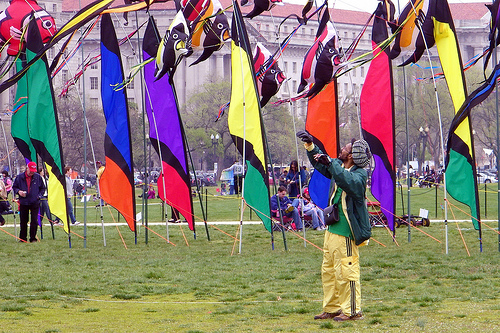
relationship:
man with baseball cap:
[11, 160, 47, 244] [26, 161, 38, 172]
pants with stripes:
[322, 228, 364, 314] [345, 233, 357, 315]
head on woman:
[286, 158, 298, 171] [284, 158, 304, 195]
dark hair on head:
[289, 159, 299, 174] [286, 158, 298, 171]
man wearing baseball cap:
[13, 160, 47, 242] [26, 160, 38, 173]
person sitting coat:
[268, 184, 306, 231] [270, 189, 292, 215]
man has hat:
[294, 130, 374, 323] [351, 137, 373, 167]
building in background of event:
[1, 1, 499, 121] [1, 0, 497, 332]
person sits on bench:
[270, 194, 294, 223] [271, 182, 322, 222]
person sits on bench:
[293, 193, 322, 231] [271, 182, 322, 222]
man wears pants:
[300, 127, 375, 317] [307, 232, 369, 321]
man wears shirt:
[300, 127, 375, 317] [300, 142, 376, 242]